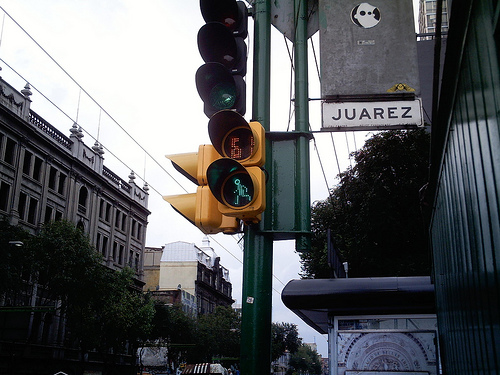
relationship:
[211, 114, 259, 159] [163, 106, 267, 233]
light of traffic light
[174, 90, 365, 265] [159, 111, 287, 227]
light of traffic light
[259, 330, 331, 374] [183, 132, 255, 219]
man on light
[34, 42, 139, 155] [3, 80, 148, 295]
power line above building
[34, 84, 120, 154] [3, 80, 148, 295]
power line above building